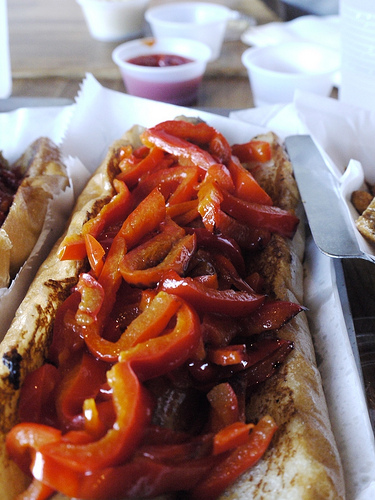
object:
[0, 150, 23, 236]
steak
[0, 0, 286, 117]
table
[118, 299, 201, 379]
red pepper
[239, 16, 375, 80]
napkin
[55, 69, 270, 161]
wrapper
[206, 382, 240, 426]
pepper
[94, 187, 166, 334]
pepper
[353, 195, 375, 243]
french fries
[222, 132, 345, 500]
bread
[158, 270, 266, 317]
red pepper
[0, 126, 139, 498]
bun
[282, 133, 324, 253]
edge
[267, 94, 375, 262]
food dish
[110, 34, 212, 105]
cup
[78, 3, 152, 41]
cup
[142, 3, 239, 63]
cup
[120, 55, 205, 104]
ketchup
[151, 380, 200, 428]
sacuce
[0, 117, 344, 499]
hot dog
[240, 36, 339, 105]
container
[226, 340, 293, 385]
onion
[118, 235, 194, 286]
red pepper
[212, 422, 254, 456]
pepper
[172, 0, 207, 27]
something